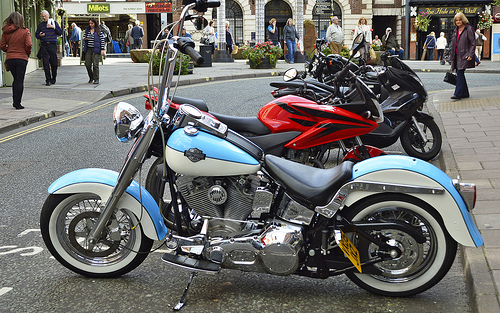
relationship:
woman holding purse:
[436, 8, 482, 103] [437, 61, 466, 96]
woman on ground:
[436, 8, 482, 103] [0, 57, 500, 313]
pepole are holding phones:
[37, 6, 73, 84] [34, 29, 92, 42]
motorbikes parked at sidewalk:
[44, 17, 492, 293] [434, 84, 483, 234]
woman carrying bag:
[436, 8, 482, 103] [439, 56, 466, 83]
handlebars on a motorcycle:
[147, 1, 221, 71] [32, 4, 479, 312]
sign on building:
[83, 2, 116, 15] [56, 2, 376, 53]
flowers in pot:
[245, 38, 277, 68] [247, 46, 277, 73]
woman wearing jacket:
[436, 8, 482, 103] [449, 20, 476, 66]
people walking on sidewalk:
[4, 8, 112, 105] [0, 47, 498, 136]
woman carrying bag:
[436, 8, 482, 103] [442, 71, 458, 85]